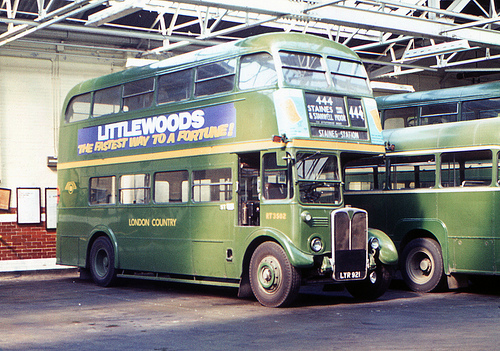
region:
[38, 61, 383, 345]
This is a large bus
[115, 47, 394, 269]
The bus is old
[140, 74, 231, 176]
The bus is double decker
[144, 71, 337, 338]
The bus has two levels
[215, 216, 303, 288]
This is a wheel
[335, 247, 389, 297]
This is a plate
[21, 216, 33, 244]
the brick is red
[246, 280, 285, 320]
this is a tire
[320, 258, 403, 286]
the plate is black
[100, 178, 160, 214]
this is a window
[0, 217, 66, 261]
bricked area of a wall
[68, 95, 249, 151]
blue ad on the side of a green bus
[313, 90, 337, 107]
number 444 on a bus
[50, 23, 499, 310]
two buses parked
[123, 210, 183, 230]
words "london country" written on bus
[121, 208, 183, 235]
yellow words on a green bus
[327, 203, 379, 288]
grill on the front of a green bus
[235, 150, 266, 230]
tall window on the side of a bus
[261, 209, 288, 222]
number written in yellow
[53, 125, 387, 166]
yellow stripe on a green bus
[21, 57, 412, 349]
a big green bus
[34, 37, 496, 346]
a double green bus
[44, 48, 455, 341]
green bus on a road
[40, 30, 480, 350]
green bus in a parking lot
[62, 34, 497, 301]
green bus sitting in a parking lot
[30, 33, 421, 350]
green bus with balck tires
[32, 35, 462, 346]
green bus with white headlights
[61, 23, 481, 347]
a shiny green bus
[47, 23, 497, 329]
a green bus that is shiny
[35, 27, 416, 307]
a big green bus in a parking lot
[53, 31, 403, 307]
a bus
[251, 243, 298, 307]
front wheel of the bus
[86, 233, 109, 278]
back wheel of the bus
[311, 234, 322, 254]
the headlight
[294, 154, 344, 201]
the windshield on the bus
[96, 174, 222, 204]
windows on the bus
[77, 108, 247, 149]
a banner on the bus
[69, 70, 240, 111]
windows on the bus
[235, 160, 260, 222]
the door on the bus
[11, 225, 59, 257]
the wall is made of bricks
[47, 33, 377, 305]
the bus is green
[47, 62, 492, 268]
the bus is a double decker bus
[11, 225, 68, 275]
the brick is red on the wall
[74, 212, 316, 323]
the tires are black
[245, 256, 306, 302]
the hubcap is green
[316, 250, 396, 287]
numbers are on the front of the bus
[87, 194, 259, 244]
yellow print is on the bus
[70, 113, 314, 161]
a sign is on the bus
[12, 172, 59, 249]
a white board is on the wall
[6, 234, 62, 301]
the baseboards are white